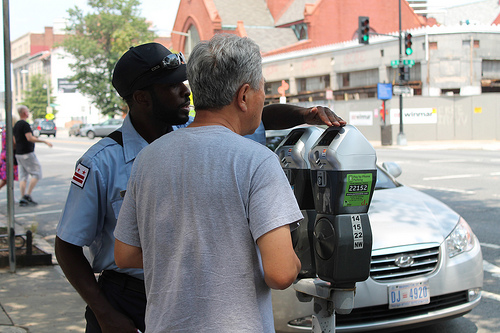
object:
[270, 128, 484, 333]
car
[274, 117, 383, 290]
meter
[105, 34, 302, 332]
man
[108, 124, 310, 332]
tshirt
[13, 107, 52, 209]
man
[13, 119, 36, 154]
shirt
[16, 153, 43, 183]
shorts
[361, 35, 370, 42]
light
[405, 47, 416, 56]
light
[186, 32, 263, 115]
hair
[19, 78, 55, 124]
tree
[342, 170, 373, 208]
sticker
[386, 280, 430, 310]
license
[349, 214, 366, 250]
sticker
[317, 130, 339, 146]
screen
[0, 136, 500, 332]
street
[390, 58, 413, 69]
sign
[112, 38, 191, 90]
hat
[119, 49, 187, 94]
sunglasses